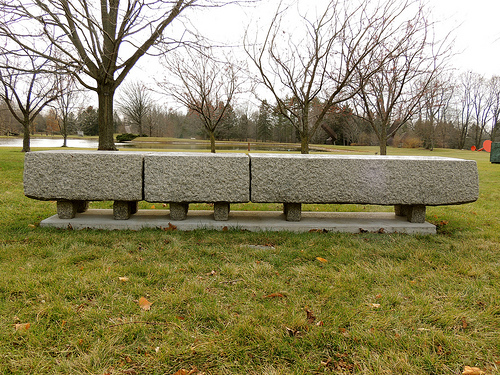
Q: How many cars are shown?
A: Zero.